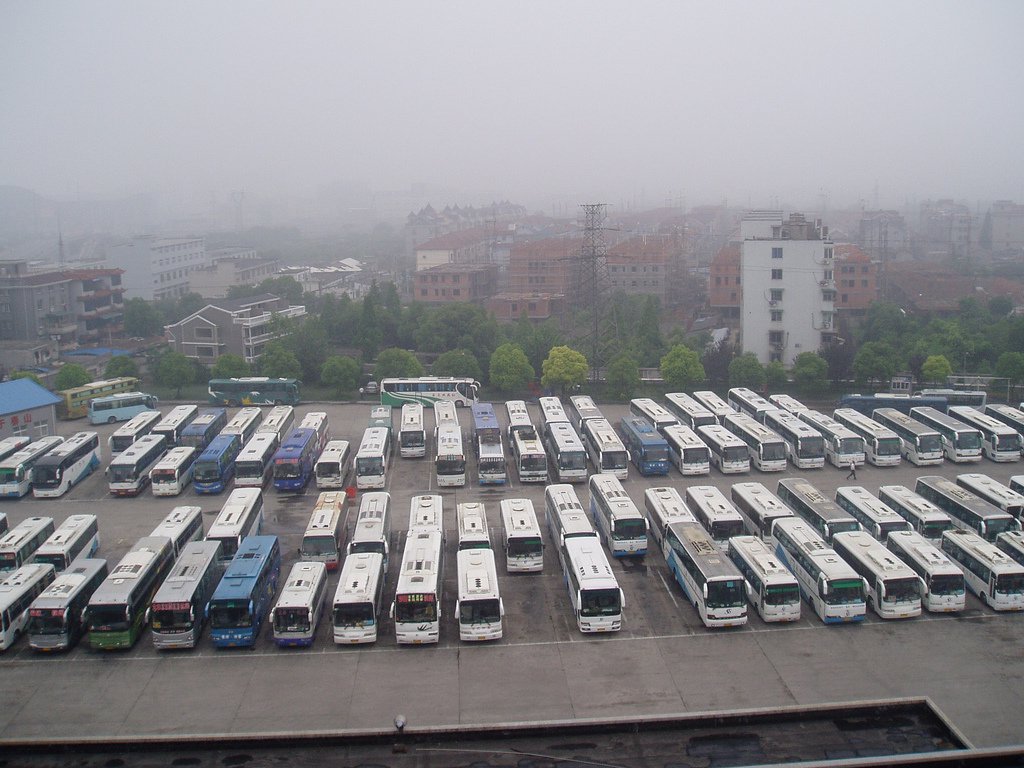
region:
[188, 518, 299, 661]
this is a blue bus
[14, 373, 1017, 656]
this is a large bus yard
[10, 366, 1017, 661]
the buses are parked in lines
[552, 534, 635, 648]
this bus is white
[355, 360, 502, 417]
this bus has wavy stripes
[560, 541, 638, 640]
a bus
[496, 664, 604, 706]
the sidewalk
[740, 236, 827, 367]
a building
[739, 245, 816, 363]
the building is white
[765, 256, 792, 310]
a window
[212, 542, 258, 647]
a blue bus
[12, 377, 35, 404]
the roof is blue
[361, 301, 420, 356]
the bush is green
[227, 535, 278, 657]
Blue bus parked in lot.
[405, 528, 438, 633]
White bus parked in lot.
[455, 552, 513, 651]
White bus parked in lot.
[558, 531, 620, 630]
White bus parked in lot.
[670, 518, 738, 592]
Top of bus is gray.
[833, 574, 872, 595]
Green stripe on front of bus.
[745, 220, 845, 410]
White building in distance.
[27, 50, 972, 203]
Sky is gray and foggy.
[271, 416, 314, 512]
Large blue bus parked in lot.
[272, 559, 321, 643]
the bus is white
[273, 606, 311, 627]
front window of bus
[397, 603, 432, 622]
wind shield of bus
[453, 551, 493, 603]
top of a bus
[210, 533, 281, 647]
the bus is blue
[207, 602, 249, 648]
the front of a bus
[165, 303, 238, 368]
brown and white building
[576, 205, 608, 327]
the tower is metal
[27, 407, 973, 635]
Buses in parking lot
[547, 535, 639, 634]
Bus in parking lot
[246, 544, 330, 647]
Bus in parking lot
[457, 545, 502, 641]
bus is big and white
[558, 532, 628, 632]
bus is big and white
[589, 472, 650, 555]
bus is big and white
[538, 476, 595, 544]
bus is big and white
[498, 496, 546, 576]
bus is big and white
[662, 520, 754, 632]
bus is big and white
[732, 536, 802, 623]
bus is big and white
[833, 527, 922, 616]
bus is big and white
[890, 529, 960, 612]
bus is big and white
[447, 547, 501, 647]
white colored bus parked on pavement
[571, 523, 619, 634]
white colored bus parked on pavement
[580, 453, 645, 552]
white colored bus parked on pavement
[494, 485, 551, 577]
white colored bus parked on pavement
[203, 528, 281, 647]
blue colored bus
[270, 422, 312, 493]
blue colored bus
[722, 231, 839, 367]
white colored building in the background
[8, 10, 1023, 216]
grey overcast sky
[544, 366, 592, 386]
green leaves on the tree